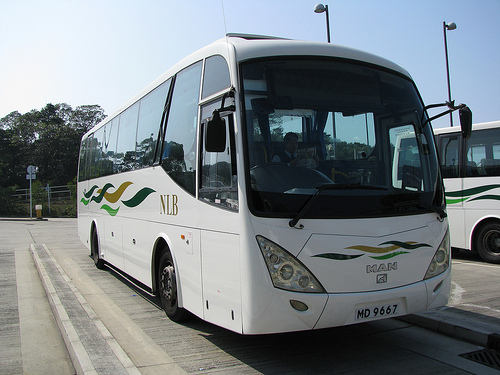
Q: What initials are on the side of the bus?
A: NLB.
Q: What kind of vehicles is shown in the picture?
A: A bus.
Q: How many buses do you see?
A: Two.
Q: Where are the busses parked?
A: In a parking lot.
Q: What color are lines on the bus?
A: Green and gold.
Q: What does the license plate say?
A: MD 9667.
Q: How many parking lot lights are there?
A: Two.